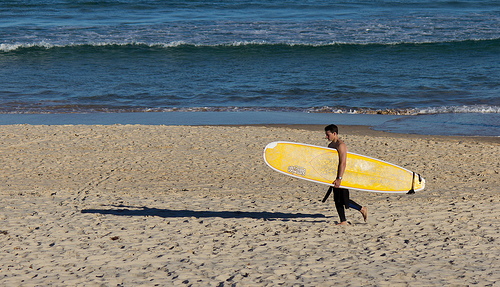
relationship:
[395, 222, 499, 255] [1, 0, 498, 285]
footprints on beach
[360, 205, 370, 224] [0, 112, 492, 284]
foot on beach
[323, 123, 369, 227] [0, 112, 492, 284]
man on beach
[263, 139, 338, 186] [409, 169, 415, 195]
surfboard has leash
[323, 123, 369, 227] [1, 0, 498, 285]
man walking on beach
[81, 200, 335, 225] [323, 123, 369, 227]
shadow of man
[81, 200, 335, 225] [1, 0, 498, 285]
shadow on beach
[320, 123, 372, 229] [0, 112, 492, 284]
man walking on beach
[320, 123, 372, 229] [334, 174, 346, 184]
man wearing watch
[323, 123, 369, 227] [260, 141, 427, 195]
man holding board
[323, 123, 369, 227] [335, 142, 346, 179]
man has arms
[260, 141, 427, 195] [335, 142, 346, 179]
board in arms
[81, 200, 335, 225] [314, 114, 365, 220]
shadow of man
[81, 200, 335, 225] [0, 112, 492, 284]
shadow on beach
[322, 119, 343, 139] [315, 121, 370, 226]
hair of surfer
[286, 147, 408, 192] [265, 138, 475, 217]
spots on yellow board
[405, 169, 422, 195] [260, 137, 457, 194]
leash on board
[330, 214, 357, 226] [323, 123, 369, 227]
foot of man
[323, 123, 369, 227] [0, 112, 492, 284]
man at beach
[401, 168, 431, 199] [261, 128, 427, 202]
tail of board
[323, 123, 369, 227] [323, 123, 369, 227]
man carrying man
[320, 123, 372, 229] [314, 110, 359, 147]
man has hair